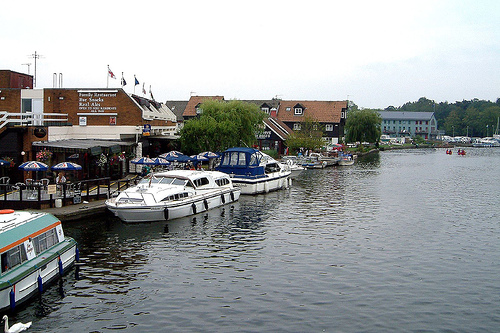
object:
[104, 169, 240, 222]
boat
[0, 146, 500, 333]
water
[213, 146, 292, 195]
boats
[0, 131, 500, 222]
pier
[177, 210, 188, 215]
white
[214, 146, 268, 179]
blue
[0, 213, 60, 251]
green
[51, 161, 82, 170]
umbrella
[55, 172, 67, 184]
person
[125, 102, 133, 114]
brown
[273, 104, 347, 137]
background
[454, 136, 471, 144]
cars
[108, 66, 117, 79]
flags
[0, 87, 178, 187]
building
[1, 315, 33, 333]
swan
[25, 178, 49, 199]
seating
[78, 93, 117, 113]
restaurant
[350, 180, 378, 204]
ripple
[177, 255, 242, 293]
ripples